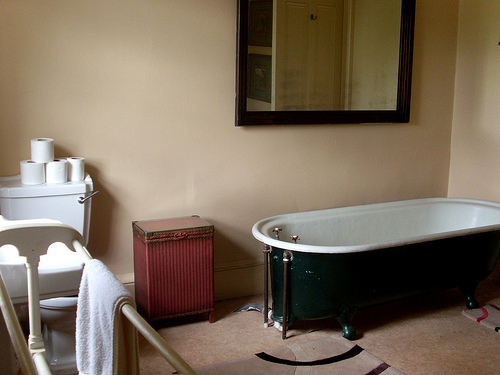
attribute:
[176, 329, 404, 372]
rug — large, for bath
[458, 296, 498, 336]
towel mat — white, red, black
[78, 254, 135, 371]
towel — large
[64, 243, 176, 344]
towel — white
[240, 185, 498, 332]
tub — green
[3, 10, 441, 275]
walls — beige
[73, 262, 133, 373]
towel — white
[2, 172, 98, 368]
toilet — white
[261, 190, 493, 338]
bathtub — old fashioned, green, showerless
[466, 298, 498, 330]
towel — one, small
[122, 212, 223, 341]
hamper — maroon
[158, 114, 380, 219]
wall — cream colored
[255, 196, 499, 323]
bathtub — white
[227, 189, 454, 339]
tub — green, white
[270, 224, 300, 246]
faucets — hot, cold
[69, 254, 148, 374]
towel — white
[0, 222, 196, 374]
rack — wooden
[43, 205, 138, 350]
clothes — burgandy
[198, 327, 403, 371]
rug — tan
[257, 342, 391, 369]
stripes — black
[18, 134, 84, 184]
toilet paper — four, in rolls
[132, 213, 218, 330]
hamper — red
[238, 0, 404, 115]
mirror — large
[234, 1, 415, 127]
mirror — large, dark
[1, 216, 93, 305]
sink — pedestal